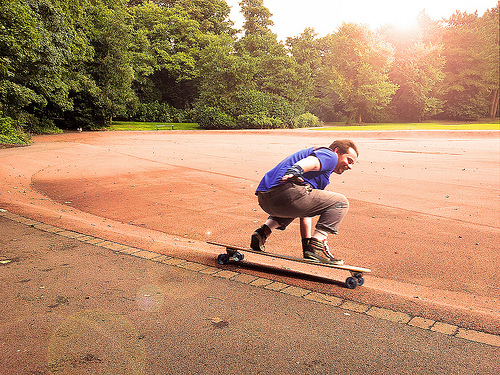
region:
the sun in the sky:
[365, 15, 411, 35]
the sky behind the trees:
[258, 4, 350, 42]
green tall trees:
[10, 3, 310, 129]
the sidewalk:
[65, 115, 450, 234]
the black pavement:
[16, 230, 274, 350]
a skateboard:
[205, 233, 373, 288]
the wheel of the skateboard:
[346, 274, 358, 285]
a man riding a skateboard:
[238, 133, 371, 279]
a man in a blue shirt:
[252, 133, 364, 259]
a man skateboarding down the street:
[223, 144, 455, 346]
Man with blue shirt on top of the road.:
[269, 155, 336, 192]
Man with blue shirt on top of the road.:
[307, 211, 325, 229]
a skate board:
[209, 240, 371, 289]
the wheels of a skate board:
[218, 250, 245, 263]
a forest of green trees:
[19, 10, 415, 123]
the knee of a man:
[328, 189, 354, 221]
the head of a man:
[331, 138, 359, 175]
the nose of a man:
[346, 163, 352, 170]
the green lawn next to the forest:
[125, 116, 186, 129]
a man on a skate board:
[241, 127, 376, 284]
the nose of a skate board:
[359, 264, 373, 282]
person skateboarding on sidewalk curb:
[206, 118, 403, 298]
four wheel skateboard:
[203, 230, 396, 307]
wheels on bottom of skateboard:
[207, 243, 369, 301]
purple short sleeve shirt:
[254, 133, 342, 202]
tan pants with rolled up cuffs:
[246, 174, 352, 237]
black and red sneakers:
[241, 219, 347, 273]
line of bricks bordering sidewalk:
[1, 211, 496, 343]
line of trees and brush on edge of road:
[2, 0, 499, 144]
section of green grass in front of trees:
[354, 117, 499, 132]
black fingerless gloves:
[283, 160, 306, 184]